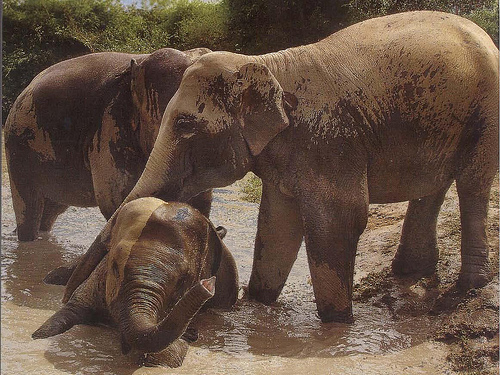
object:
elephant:
[6, 48, 224, 251]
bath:
[31, 197, 242, 367]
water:
[0, 121, 457, 374]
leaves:
[90, 1, 233, 53]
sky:
[93, 0, 225, 13]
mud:
[322, 205, 490, 373]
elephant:
[62, 9, 500, 324]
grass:
[236, 170, 263, 204]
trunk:
[109, 274, 217, 354]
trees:
[220, 0, 494, 108]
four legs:
[246, 188, 494, 323]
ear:
[238, 64, 294, 157]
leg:
[281, 158, 371, 324]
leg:
[31, 299, 89, 341]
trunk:
[60, 153, 212, 297]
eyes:
[109, 259, 123, 279]